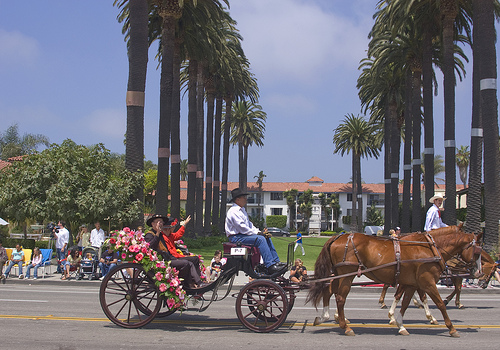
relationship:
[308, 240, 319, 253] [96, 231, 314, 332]
grass are on carriage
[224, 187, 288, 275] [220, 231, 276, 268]
guy wearing pants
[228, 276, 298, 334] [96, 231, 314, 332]
wheels are in front of carriage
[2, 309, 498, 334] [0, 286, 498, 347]
lines are on asphalt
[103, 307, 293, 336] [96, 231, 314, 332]
shadow from carriage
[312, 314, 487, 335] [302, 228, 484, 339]
shadow from horse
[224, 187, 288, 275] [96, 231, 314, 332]
guy riding a carriage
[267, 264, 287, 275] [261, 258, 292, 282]
feet are on feet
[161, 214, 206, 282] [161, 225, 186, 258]
person wearing clothes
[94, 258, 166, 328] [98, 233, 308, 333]
wheel on carraige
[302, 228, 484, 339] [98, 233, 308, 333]
horse pulling carraige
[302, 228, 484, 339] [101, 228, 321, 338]
horse pulling carriage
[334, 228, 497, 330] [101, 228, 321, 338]
horse pulling carriage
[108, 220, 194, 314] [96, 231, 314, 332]
flowers are decorating carriage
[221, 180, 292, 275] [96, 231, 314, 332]
guy driving a carriage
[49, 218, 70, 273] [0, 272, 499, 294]
person standing on sidewalk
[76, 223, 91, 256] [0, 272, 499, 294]
person standing on sidewalk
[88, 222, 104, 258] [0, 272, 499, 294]
person standing on sidewalk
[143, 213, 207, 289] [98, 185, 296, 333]
man in carriage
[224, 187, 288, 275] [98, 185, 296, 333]
guy in carriage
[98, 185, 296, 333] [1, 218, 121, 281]
carriage passing audience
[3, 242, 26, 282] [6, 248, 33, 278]
kid sitting in chair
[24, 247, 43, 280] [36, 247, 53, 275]
girl sitting in chair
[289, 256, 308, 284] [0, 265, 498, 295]
person sitting on sidewalk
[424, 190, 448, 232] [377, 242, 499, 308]
man riding horse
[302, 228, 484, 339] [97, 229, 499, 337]
horse pulling carriage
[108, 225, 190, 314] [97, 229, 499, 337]
flowers on carriage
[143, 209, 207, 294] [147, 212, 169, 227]
man wearing hat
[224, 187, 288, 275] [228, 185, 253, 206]
guy wearing hat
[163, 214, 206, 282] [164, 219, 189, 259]
person wearing clothes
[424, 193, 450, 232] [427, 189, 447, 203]
man wearing hat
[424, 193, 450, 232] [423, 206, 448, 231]
man wearing shirt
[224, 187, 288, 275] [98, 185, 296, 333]
guy sitting in front of carriage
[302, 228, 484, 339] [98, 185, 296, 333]
horse pulling carriage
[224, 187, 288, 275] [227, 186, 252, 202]
guy wearing hat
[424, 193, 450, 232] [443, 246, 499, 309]
man riding horse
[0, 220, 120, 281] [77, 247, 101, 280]
audience sitting in stroller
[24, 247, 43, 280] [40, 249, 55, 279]
girl sitting in chair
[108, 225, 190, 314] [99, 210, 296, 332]
flowers on side of carriage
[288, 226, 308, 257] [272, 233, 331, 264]
man walking across grass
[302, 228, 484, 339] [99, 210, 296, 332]
horse are pulling carriage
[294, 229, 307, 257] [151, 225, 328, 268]
man on field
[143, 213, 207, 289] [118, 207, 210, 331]
man in chair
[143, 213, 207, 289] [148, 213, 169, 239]
man waving h hand